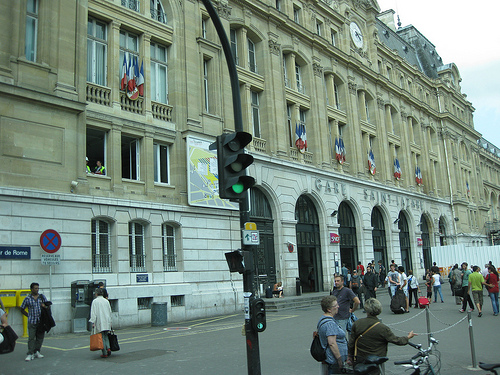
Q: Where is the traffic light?
A: On pole.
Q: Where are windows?
A: On the building.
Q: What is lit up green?
A: Traffic light.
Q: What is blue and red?
A: A street sign.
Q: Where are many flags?
A: On the building.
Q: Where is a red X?
A: On a sign.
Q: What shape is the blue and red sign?
A: Circle.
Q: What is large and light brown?
A: A building.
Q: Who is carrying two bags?
A: Person in white coat.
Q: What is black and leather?
A: Bicycle seats.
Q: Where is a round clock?
A: Near the top of the building.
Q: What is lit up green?
A: A traffic light.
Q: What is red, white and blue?
A: Flags.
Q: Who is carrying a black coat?
A: Man on the left.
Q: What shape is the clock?
A: Round.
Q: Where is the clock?
A: Near the top of the building.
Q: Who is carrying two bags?
A: Woman in white coat.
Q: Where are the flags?
A: In front of the windows.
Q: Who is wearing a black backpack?
A: Woman in blue shirt.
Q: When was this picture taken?
A: Daytime.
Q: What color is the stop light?
A: Green.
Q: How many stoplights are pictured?
A: 2.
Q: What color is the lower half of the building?
A: White.